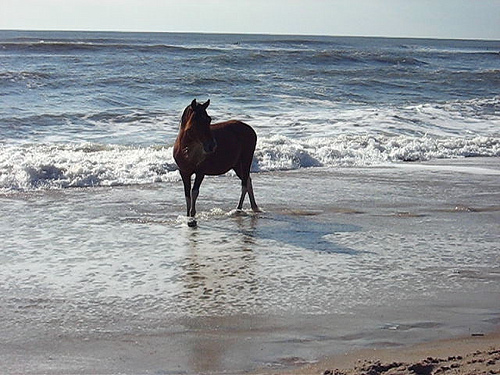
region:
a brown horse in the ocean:
[161, 91, 281, 236]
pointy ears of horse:
[182, 89, 216, 113]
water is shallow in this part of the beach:
[7, 176, 488, 307]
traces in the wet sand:
[354, 339, 499, 373]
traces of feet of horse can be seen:
[254, 191, 498, 233]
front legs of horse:
[173, 173, 207, 225]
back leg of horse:
[234, 166, 263, 220]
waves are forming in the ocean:
[9, 29, 496, 94]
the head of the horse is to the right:
[159, 85, 277, 233]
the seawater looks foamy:
[0, 141, 153, 186]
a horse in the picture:
[173, 98, 270, 224]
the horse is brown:
[165, 95, 265, 225]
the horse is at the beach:
[0, 30, 495, 370]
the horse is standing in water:
[156, 90, 287, 232]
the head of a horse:
[166, 97, 224, 147]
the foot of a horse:
[187, 175, 202, 230]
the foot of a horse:
[235, 165, 250, 217]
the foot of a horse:
[245, 180, 265, 212]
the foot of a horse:
[178, 170, 188, 210]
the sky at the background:
[0, 1, 498, 41]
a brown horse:
[170, 88, 181, 107]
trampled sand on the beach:
[317, 331, 497, 372]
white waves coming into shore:
[6, 96, 496, 194]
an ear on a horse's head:
[189, 97, 197, 108]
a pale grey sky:
[1, 2, 496, 37]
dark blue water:
[0, 30, 498, 114]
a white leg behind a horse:
[244, 176, 267, 217]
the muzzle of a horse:
[199, 111, 216, 153]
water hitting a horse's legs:
[171, 201, 264, 230]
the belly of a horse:
[204, 141, 242, 176]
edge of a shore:
[313, 230, 372, 279]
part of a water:
[195, 235, 263, 312]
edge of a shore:
[282, 306, 342, 323]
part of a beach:
[436, 333, 474, 368]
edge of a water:
[213, 277, 272, 320]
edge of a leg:
[238, 187, 258, 219]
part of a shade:
[314, 223, 388, 340]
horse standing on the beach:
[95, 78, 348, 259]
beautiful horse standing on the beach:
[82, 76, 377, 274]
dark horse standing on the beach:
[73, 67, 355, 290]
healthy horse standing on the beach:
[72, 58, 334, 260]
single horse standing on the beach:
[132, 85, 324, 264]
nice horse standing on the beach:
[112, 63, 308, 283]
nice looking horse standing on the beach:
[95, 75, 325, 282]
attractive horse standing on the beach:
[102, 68, 326, 272]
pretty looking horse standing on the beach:
[127, 77, 304, 262]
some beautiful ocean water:
[280, 43, 457, 177]